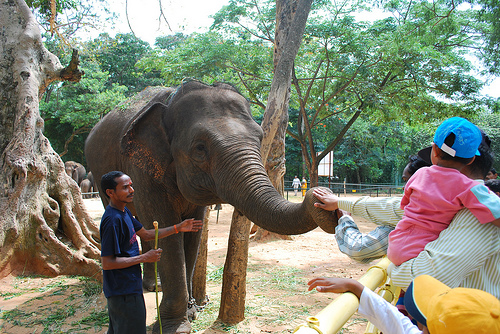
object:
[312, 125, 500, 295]
person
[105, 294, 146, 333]
pants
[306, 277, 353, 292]
man's hand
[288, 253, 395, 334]
fence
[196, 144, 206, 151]
eye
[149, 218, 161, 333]
stick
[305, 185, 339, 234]
blanket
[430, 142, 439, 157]
ear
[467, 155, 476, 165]
ear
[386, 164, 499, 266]
outfit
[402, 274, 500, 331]
cap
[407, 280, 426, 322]
stripe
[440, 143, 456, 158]
snap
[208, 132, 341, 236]
trunk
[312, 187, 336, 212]
hand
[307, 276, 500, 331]
child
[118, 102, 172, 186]
ear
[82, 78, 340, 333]
elephant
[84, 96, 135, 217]
belly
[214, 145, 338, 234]
trunk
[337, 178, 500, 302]
shirt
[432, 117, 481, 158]
baseball cap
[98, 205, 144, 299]
t shirt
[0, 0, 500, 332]
zoo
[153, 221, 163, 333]
stick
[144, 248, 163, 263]
hand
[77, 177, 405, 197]
fence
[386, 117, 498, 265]
baby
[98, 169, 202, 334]
man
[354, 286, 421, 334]
shirt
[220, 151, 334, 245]
trunk